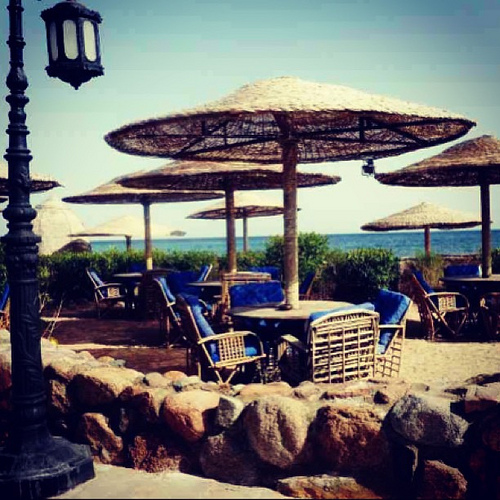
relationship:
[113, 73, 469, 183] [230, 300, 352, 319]
umbrella above table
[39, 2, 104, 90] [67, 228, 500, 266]
lamp above water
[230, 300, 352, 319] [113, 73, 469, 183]
table below umbrella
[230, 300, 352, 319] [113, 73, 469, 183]
table under umbrella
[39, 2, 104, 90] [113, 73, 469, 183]
lamp near umbrella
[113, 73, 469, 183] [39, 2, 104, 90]
umbrella near lamp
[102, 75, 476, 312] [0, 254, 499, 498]
umbrella in cabana area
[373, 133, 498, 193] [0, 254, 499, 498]
umbrella in cabana area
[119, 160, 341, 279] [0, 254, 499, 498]
umbrella in cabana area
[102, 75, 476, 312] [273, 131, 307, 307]
umbrella on pole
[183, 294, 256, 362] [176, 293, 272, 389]
cushion on chair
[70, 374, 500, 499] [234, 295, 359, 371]
wall by table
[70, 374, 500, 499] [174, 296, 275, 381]
wall by chair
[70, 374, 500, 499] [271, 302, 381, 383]
wall by chair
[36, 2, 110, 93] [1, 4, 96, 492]
lamp on pole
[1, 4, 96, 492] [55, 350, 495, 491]
pole by wall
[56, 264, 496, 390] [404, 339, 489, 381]
cabana area has sand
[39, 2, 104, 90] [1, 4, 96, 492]
lamp on pole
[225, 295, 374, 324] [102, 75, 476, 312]
table under umbrella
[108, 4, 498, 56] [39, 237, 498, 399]
sky under beach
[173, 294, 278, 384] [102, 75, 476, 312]
chairs under umbrella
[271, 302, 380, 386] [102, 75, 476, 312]
chairs under umbrella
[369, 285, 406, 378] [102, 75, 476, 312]
chairs under umbrella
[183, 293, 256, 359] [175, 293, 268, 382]
cushion on chair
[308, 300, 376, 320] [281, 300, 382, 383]
cushion on chair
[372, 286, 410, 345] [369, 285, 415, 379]
cushion on chair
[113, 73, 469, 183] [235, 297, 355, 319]
umbrella over table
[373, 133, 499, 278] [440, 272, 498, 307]
umbrella over table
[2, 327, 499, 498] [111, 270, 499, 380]
wall in front of tables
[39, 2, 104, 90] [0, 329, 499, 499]
lamp overhanging rocks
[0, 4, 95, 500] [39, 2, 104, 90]
pole holding lamp